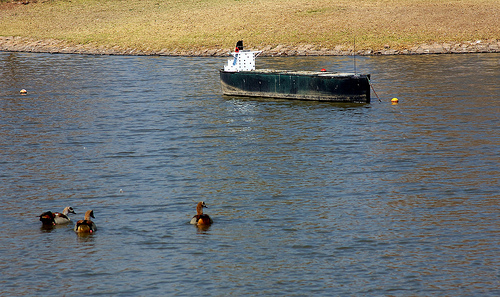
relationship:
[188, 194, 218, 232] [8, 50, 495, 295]
duck in lake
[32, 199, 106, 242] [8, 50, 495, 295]
ducks in lake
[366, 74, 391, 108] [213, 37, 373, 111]
string on boat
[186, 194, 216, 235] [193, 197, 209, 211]
duck has head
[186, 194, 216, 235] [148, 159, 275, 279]
duck in water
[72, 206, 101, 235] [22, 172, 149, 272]
mallar in water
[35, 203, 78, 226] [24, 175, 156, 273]
duck in water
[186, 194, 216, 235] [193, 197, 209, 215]
duck has head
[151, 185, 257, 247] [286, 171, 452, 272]
duck in water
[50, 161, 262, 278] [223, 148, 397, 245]
ducks in water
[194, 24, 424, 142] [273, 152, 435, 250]
boat in water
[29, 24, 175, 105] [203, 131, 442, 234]
shore of water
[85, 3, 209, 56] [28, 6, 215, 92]
grass on beach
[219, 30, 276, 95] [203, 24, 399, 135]
cover on boat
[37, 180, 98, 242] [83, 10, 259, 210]
duck for food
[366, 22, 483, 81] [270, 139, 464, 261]
rocks by water